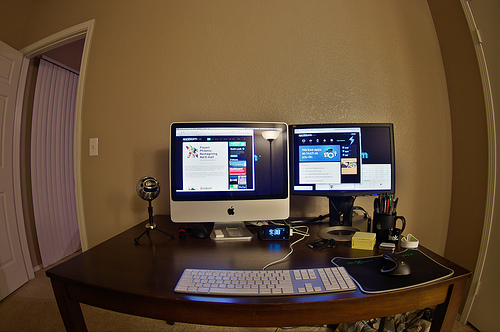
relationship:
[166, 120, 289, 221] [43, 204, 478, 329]
screen on desk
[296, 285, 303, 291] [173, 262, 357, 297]
key on keyboard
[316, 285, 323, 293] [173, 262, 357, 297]
key on keyboard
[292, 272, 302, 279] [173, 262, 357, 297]
key on keyboard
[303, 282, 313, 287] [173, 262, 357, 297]
key on keyboard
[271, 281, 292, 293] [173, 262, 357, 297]
key on keyboard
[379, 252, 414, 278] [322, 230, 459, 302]
computer mouse on mouse pad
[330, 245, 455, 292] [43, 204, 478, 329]
mousepad on desk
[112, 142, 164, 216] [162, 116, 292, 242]
webcam next to monitor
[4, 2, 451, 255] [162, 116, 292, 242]
wall behind monitor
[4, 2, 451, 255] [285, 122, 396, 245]
wall behind monitor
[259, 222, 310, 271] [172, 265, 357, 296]
cable attached to keyboard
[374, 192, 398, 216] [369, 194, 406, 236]
pen in mug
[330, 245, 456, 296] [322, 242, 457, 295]
trim on mouse pad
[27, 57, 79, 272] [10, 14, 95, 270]
door on doorway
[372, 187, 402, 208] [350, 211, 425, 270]
pen fills cup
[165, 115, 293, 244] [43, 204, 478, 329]
computer monitor on desk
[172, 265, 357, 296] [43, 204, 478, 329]
keyboard on desk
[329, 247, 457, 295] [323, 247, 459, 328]
border on mouse pad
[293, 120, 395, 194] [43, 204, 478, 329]
monitor on desk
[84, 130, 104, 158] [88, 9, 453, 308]
switch on wall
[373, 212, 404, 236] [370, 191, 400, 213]
cup of pens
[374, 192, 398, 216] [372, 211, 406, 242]
pen in cup